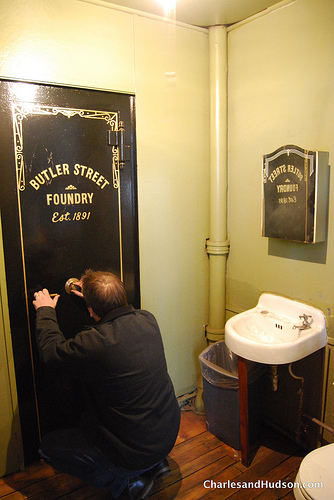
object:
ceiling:
[193, 5, 236, 23]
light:
[156, 1, 175, 19]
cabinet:
[259, 143, 329, 246]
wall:
[236, 32, 319, 118]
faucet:
[292, 313, 314, 331]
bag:
[197, 339, 264, 391]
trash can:
[198, 339, 242, 451]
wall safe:
[141, 23, 170, 213]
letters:
[46, 192, 94, 223]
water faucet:
[291, 313, 313, 331]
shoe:
[116, 473, 153, 499]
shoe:
[140, 458, 171, 483]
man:
[33, 267, 184, 499]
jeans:
[39, 443, 164, 498]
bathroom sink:
[215, 275, 329, 400]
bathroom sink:
[223, 291, 327, 468]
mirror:
[261, 143, 315, 242]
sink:
[223, 291, 328, 365]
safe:
[0, 77, 141, 470]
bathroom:
[0, 1, 334, 500]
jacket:
[31, 304, 181, 471]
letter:
[29, 179, 41, 191]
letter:
[34, 173, 45, 185]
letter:
[40, 168, 50, 180]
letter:
[48, 167, 58, 179]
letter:
[55, 164, 63, 176]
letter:
[62, 163, 70, 175]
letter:
[46, 194, 52, 206]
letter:
[67, 193, 74, 206]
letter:
[81, 192, 94, 205]